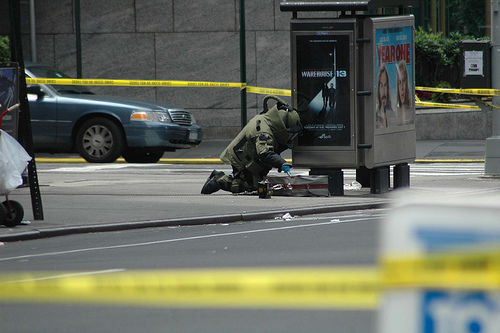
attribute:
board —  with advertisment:
[362, 12, 420, 167]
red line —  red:
[266, 185, 330, 188]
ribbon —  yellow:
[18, 70, 290, 98]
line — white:
[115, 217, 359, 239]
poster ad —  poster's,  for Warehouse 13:
[291, 35, 352, 147]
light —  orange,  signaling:
[131, 110, 149, 119]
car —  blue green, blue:
[0, 59, 205, 163]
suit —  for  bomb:
[216, 110, 285, 187]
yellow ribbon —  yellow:
[30, 74, 290, 100]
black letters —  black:
[32, 80, 284, 91]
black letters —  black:
[426, 90, 489, 92]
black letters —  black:
[437, 105, 469, 109]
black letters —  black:
[11, 279, 359, 296]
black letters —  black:
[403, 258, 495, 275]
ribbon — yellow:
[22, 72, 499, 112]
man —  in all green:
[160, 67, 372, 274]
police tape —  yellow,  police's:
[23, 249, 378, 331]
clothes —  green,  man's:
[226, 112, 294, 177]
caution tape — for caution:
[0, 254, 499, 304]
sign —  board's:
[375, 31, 409, 128]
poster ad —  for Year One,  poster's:
[372, 21, 416, 137]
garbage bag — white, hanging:
[1, 134, 35, 172]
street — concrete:
[4, 133, 499, 331]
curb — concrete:
[2, 175, 399, 251]